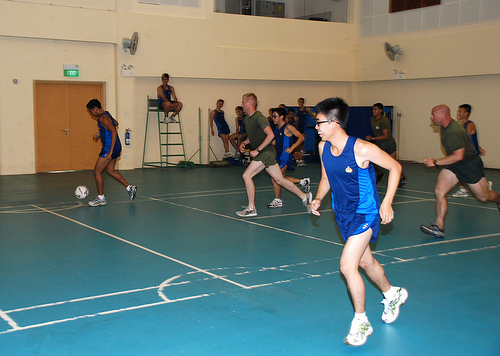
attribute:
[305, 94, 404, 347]
man — running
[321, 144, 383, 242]
uniform — blue, two blues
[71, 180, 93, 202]
ball — kicked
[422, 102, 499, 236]
man — white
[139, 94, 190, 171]
chair — tall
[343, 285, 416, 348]
shoes — white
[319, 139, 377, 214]
jersey — blue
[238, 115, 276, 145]
shirt — green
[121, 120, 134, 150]
fire extinguisher — blue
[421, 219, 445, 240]
shoe — black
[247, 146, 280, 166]
shorts — green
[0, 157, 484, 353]
floor — white, blue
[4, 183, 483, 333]
lines — white